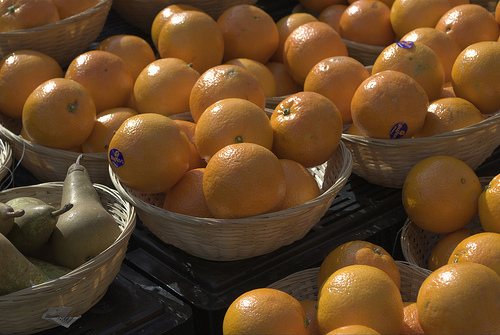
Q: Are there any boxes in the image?
A: No, there are no boxes.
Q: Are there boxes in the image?
A: No, there are no boxes.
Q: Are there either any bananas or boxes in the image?
A: No, there are no boxes or bananas.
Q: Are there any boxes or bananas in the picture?
A: No, there are no boxes or bananas.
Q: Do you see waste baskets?
A: No, there are no waste baskets.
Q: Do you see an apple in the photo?
A: No, there are no apples.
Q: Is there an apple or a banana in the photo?
A: No, there are no apples or bananas.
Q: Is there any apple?
A: No, there are no apples.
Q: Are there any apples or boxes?
A: No, there are no apples or boxes.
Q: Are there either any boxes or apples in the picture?
A: No, there are no apples or boxes.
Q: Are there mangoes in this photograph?
A: No, there are no mangoes.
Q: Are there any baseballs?
A: No, there are no baseballs.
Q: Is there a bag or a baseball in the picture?
A: No, there are no baseballs or bags.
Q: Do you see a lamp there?
A: No, there are no lamps.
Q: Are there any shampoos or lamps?
A: No, there are no lamps or shampoos.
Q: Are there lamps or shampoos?
A: No, there are no lamps or shampoos.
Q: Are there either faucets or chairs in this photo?
A: No, there are no chairs or faucets.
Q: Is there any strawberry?
A: No, there are no strawberries.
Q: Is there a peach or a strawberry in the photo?
A: No, there are no strawberries or peaches.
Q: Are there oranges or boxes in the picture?
A: Yes, there are oranges.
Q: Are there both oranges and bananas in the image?
A: No, there are oranges but no bananas.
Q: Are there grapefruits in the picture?
A: No, there are no grapefruits.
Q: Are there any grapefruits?
A: No, there are no grapefruits.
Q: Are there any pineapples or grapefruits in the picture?
A: No, there are no grapefruits or pineapples.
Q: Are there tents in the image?
A: No, there are no tents.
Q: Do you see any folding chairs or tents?
A: No, there are no tents or folding chairs.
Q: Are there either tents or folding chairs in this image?
A: No, there are no tents or folding chairs.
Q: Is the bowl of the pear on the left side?
A: Yes, the bowl is on the left of the image.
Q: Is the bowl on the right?
A: No, the bowl is on the left of the image.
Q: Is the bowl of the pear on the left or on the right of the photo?
A: The bowl is on the left of the image.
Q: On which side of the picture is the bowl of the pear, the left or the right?
A: The bowl is on the left of the image.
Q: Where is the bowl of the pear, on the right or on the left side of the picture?
A: The bowl is on the left of the image.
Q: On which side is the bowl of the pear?
A: The bowl is on the left of the image.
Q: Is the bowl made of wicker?
A: Yes, the bowl is made of wicker.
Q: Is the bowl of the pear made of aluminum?
A: No, the bowl is made of wicker.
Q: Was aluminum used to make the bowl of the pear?
A: No, the bowl is made of wicker.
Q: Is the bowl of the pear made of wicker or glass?
A: The bowl is made of wicker.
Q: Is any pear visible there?
A: Yes, there is a pear.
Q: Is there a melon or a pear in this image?
A: Yes, there is a pear.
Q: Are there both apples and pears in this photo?
A: No, there is a pear but no apples.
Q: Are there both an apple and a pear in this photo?
A: No, there is a pear but no apples.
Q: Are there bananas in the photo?
A: No, there are no bananas.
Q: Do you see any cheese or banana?
A: No, there are no bananas or cheese.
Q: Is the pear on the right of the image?
A: No, the pear is on the left of the image.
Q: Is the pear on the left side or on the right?
A: The pear is on the left of the image.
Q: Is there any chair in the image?
A: No, there are no chairs.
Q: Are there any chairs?
A: No, there are no chairs.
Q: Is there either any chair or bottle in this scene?
A: No, there are no chairs or bottles.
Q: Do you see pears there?
A: Yes, there is a pear.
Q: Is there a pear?
A: Yes, there is a pear.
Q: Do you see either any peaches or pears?
A: Yes, there is a pear.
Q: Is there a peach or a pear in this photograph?
A: Yes, there is a pear.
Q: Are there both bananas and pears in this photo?
A: No, there is a pear but no bananas.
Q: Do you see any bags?
A: No, there are no bags.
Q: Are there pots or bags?
A: No, there are no bags or pots.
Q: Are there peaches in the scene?
A: No, there are no peaches.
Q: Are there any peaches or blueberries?
A: No, there are no peaches or blueberries.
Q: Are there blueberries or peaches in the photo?
A: No, there are no peaches or blueberries.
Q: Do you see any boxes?
A: No, there are no boxes.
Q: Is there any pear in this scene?
A: Yes, there is a pear.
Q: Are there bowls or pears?
A: Yes, there is a pear.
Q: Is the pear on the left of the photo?
A: Yes, the pear is on the left of the image.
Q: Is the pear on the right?
A: No, the pear is on the left of the image.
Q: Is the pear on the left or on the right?
A: The pear is on the left of the image.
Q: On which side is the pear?
A: The pear is on the left of the image.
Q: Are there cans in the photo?
A: No, there are no cans.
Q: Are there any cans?
A: No, there are no cans.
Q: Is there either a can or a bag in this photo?
A: No, there are no cans or bags.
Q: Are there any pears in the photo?
A: Yes, there is a pear.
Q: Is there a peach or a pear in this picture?
A: Yes, there is a pear.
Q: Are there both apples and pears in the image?
A: No, there is a pear but no apples.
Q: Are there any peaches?
A: No, there are no peaches.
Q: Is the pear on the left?
A: Yes, the pear is on the left of the image.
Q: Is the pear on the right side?
A: No, the pear is on the left of the image.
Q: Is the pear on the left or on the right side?
A: The pear is on the left of the image.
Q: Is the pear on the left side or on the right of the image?
A: The pear is on the left of the image.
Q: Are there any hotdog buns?
A: No, there are no hotdog buns.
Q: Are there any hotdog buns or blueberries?
A: No, there are no hotdog buns or blueberries.